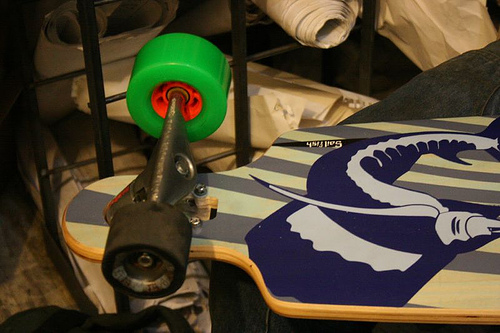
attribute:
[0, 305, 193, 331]
bag — green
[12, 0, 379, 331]
shelf — black, iron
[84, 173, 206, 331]
skateboard wheel — black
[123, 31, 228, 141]
wheel — red inside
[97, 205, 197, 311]
wheel — black, long board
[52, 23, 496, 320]
board — upside down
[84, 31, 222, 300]
wheels — green, black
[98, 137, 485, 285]
skateboard — blue, white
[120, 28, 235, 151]
wheel — black, green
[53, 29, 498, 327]
skateboard — upside-down